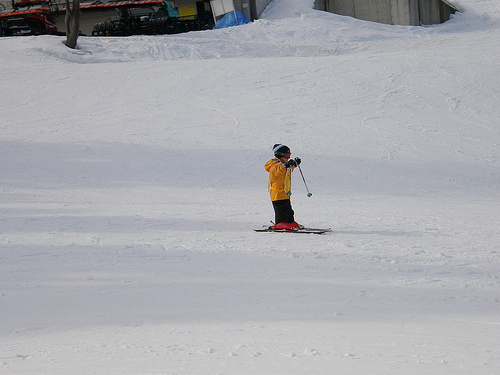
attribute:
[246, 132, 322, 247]
boy — skiing, white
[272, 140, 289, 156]
hat — black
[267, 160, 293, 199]
coat — yellow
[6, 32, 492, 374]
snow — white